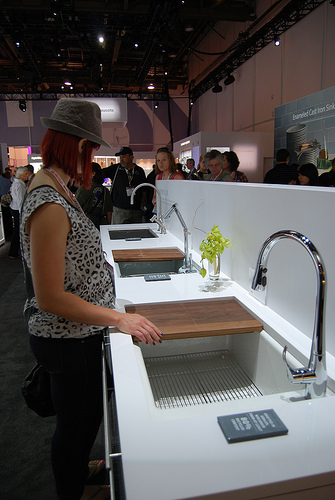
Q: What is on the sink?
A: Board.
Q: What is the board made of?
A: Wood.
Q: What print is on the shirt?
A: Cheetah.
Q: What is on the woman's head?
A: Hat.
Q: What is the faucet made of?
A: Chrome.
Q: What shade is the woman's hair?
A: Red.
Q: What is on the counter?
A: Book.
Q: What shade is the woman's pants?
A: Black.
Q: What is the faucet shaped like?
A: Hook.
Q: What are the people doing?
A: They are watching someone.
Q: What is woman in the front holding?
A: Cutting board.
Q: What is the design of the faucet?
A: Curved.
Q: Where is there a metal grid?
A: Bottom of sink.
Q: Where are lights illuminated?
A: On ceiling.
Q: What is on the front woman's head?
A: Hat.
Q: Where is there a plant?
A: On counter.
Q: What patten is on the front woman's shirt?
A: Cheetah.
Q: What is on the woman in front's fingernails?
A: Black polish.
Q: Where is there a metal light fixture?
A: Ceiling.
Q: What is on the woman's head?
A: A gray hat.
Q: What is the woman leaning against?
A: The white counter.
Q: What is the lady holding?
A: Cutting board.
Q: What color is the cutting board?
A: Brown.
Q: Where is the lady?
A: At a convention.